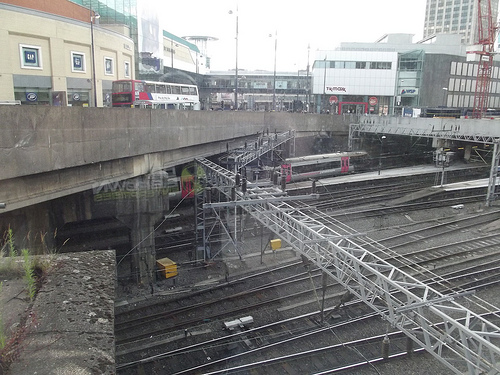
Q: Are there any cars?
A: No, there are no cars.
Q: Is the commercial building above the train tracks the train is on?
A: Yes, the building is above the train tracks.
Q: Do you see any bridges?
A: Yes, there is a bridge.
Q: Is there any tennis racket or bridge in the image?
A: Yes, there is a bridge.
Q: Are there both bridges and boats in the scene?
A: No, there is a bridge but no boats.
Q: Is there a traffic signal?
A: No, there are no traffic lights.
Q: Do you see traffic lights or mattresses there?
A: No, there are no traffic lights or mattresses.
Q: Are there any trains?
A: Yes, there is a train.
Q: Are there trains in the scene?
A: Yes, there is a train.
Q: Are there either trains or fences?
A: Yes, there is a train.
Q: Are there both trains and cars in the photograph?
A: No, there is a train but no cars.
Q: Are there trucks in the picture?
A: No, there are no trucks.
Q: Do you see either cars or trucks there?
A: No, there are no trucks or cars.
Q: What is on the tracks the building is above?
A: The train is on the tracks.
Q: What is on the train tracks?
A: The train is on the tracks.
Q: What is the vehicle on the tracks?
A: The vehicle is a train.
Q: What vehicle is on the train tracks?
A: The vehicle is a train.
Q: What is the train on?
A: The train is on the train tracks.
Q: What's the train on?
A: The train is on the train tracks.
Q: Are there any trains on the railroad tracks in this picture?
A: Yes, there is a train on the railroad tracks.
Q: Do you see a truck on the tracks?
A: No, there is a train on the tracks.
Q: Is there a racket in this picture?
A: No, there are no rackets.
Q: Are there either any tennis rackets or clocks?
A: No, there are no tennis rackets or clocks.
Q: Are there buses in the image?
A: Yes, there is a bus.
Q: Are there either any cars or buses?
A: Yes, there is a bus.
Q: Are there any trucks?
A: No, there are no trucks.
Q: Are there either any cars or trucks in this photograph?
A: No, there are no trucks or cars.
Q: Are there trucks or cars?
A: No, there are no trucks or cars.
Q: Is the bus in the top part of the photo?
A: Yes, the bus is in the top of the image.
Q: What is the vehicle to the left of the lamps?
A: The vehicle is a bus.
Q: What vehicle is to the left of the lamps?
A: The vehicle is a bus.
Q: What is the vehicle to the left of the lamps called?
A: The vehicle is a bus.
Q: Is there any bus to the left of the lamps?
A: Yes, there is a bus to the left of the lamps.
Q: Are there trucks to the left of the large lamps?
A: No, there is a bus to the left of the lamps.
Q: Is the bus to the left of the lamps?
A: Yes, the bus is to the left of the lamps.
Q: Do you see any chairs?
A: No, there are no chairs.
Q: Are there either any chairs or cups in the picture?
A: No, there are no chairs or cups.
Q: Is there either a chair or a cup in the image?
A: No, there are no chairs or cups.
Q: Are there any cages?
A: No, there are no cages.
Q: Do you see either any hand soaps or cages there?
A: No, there are no cages or hand soaps.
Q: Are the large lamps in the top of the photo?
A: Yes, the lamps are in the top of the image.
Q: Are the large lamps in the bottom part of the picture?
A: No, the lamps are in the top of the image.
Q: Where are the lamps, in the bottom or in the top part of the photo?
A: The lamps are in the top of the image.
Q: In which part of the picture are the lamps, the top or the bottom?
A: The lamps are in the top of the image.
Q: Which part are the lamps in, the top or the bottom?
A: The lamps are in the top of the image.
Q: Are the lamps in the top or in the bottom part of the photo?
A: The lamps are in the top of the image.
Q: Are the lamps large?
A: Yes, the lamps are large.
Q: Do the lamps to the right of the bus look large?
A: Yes, the lamps are large.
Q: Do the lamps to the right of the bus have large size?
A: Yes, the lamps are large.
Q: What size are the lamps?
A: The lamps are large.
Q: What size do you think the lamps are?
A: The lamps are large.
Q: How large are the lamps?
A: The lamps are large.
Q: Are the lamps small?
A: No, the lamps are large.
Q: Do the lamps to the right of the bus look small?
A: No, the lamps are large.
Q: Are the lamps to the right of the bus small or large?
A: The lamps are large.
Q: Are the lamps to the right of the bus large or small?
A: The lamps are large.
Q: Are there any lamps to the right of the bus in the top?
A: Yes, there are lamps to the right of the bus.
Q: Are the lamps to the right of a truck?
A: No, the lamps are to the right of the bus.